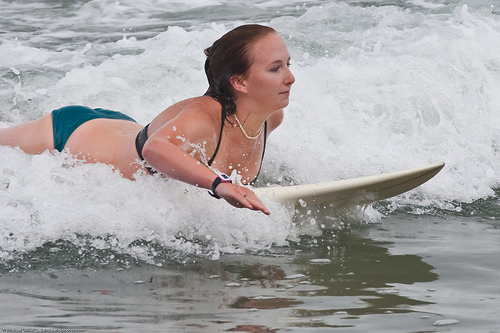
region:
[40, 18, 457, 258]
woman out riding the waves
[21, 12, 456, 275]
lady out riding the waves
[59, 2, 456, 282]
female out riding the waves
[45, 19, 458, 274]
female person out riding the waves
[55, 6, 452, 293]
woman out riding the nice waves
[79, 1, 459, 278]
woman out riding the calm waves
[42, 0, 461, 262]
woman out riding the ocean waves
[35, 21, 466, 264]
lady riding the nice waves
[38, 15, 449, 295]
female person riding ocean waves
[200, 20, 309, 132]
head of a woman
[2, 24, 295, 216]
woman in a bikini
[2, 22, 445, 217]
woman lying down on a surfboard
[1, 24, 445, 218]
young woman surfboarding at the beach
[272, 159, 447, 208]
front of a white surfboard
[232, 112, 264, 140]
necklace around the woman's neck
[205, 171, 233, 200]
waterproof watch on lady's wrist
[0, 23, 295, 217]
woman in a blue and black bikini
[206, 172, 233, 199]
wrist watch on young woman's right wrist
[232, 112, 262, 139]
gold chain on the woman's neck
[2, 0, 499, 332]
photo of a woman surfing on a white surfboard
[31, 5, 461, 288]
Young woman laying on surfboard.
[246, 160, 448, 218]
A white surfboard.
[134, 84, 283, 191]
Bikini top on woman.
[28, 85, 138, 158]
Bikini bottoms on woman.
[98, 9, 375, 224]
Woman paddling with her arms.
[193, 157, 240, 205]
Watch on woman's right wrist.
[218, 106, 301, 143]
White necklace around woman's neck.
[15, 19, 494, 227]
White foam on ocean waves.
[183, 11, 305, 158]
Woman with long hair.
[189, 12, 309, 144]
Woman with wet hair.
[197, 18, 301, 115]
the head of a person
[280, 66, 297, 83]
the nose of a person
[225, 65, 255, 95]
the ear of a person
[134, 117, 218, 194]
the arm of a person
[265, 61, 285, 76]
the eye of a person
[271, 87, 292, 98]
the mouth of a person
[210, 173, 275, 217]
the hand of a person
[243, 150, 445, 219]
a white surfboard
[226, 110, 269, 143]
a white necklace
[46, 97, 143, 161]
a blue bikini bottom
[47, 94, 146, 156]
a blue bikini bottom.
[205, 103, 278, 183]
a blue bikini top.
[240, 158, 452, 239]
a white surfboard.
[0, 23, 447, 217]
a red haired woman riding a surfboard.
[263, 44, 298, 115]
the face of a young lady.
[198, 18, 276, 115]
red hair on a woman.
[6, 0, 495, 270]
a foamy ocean wave.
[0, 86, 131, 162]
the read end of a woman.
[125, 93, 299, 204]
the torso of a woman.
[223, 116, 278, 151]
a woman wearing a necklace.